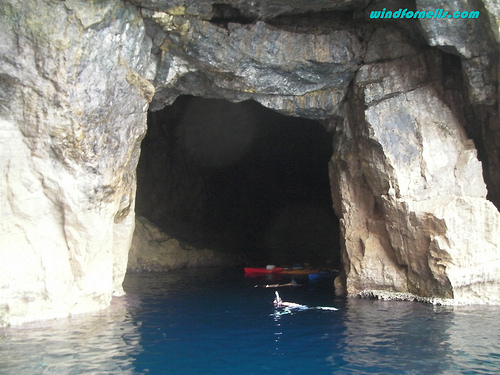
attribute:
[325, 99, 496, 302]
wall — stone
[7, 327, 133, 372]
water — rippled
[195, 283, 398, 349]
water — blue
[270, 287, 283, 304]
snorkel — white